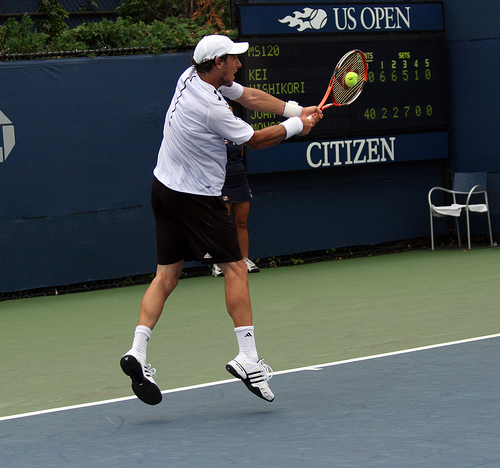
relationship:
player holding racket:
[128, 10, 298, 232] [305, 33, 391, 149]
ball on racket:
[340, 64, 364, 98] [305, 33, 391, 149]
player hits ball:
[128, 10, 298, 232] [340, 64, 364, 98]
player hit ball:
[128, 10, 298, 232] [340, 64, 364, 98]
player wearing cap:
[128, 10, 298, 232] [184, 26, 247, 78]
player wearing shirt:
[128, 10, 298, 232] [146, 62, 250, 216]